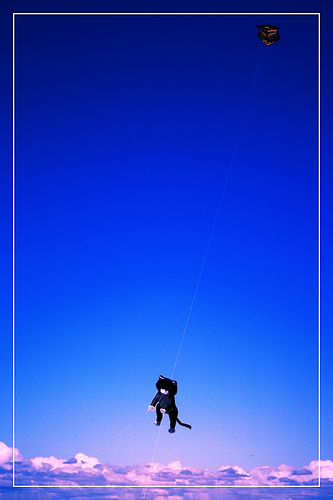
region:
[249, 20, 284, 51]
Kite in the sky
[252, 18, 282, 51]
Kite is yellow and green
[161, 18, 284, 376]
Kite has white string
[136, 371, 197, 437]
Figure of a black cat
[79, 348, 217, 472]
Cat is holding by white strings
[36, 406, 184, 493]
White strings holding a cat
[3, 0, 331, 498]
Cat is in the middle of kite and strings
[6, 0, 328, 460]
Sky is blue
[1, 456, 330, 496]
Clouds below blue sky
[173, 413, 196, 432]
Tail of cat is black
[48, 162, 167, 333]
bright blue clear sky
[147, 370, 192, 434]
large black stuffed cat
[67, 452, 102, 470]
white puffy cloud top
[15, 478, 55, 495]
dark black storm cloud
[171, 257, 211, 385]
white string attached to cat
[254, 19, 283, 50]
badge shaped kite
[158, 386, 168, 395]
white snout on black cat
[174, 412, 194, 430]
long black cat tail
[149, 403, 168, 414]
white paws on black cat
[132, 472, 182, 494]
purple hue on cloud tops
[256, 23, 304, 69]
a weird logo up top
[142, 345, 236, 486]
someone skydiving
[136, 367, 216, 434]
someone dressed as a cat skydiving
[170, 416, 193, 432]
a tail of a cat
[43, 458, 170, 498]
clouds in the sky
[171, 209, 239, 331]
string attached to the parachute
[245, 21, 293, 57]
a parachute up top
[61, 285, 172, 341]
nice blue skies in the background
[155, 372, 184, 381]
ears of the dressed up sky diver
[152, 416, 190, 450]
legs of th sky diver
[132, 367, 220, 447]
A black cat flies in the sky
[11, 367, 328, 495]
The cat is above the clouds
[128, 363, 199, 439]
The cat has white paws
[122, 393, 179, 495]
There are strings attached to each front paw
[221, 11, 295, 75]
The kite is black and yellow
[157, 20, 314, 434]
The kite is attached to the cat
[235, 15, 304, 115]
The kite has multiple strings attached to the bottom of it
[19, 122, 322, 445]
The sky is bright blue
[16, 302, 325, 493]
There is a white thin border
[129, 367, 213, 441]
The black cat has a white mouth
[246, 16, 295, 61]
square floating in the air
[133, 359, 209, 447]
stuffed animal kitty cat flying in air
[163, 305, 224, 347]
string holding a cat aloft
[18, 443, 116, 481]
purple and white clouds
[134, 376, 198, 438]
stuffed cat wearing a sweater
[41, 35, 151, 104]
clear blue sky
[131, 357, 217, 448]
cat with white paws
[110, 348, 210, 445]
cat with a black tail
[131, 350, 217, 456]
cat flying through the air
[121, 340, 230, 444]
black and white stuffed animal